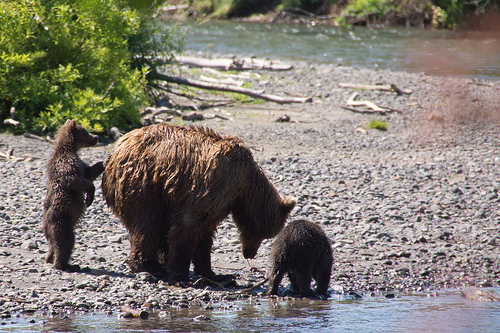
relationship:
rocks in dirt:
[357, 148, 456, 248] [304, 130, 468, 232]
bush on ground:
[2, 1, 163, 136] [1, 3, 498, 310]